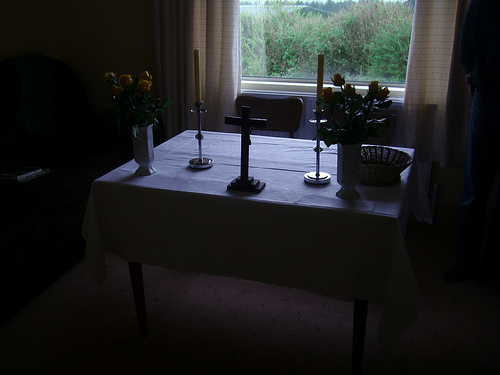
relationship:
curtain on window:
[160, 0, 243, 135] [241, 5, 410, 90]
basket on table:
[357, 146, 411, 189] [87, 128, 416, 361]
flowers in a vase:
[97, 70, 164, 128] [131, 126, 166, 179]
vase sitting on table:
[131, 126, 166, 179] [87, 128, 416, 361]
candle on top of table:
[191, 47, 204, 101] [87, 128, 416, 361]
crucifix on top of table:
[219, 103, 270, 197] [87, 128, 416, 361]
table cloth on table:
[78, 125, 427, 337] [87, 128, 416, 361]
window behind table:
[241, 5, 410, 90] [87, 128, 416, 361]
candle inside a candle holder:
[191, 47, 204, 101] [190, 102, 214, 170]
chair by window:
[232, 91, 301, 139] [241, 5, 410, 90]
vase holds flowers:
[131, 126, 166, 179] [97, 70, 164, 128]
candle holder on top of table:
[190, 102, 214, 170] [87, 128, 416, 361]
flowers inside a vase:
[97, 70, 164, 128] [131, 126, 166, 179]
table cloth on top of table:
[78, 125, 427, 337] [87, 128, 416, 361]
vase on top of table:
[131, 126, 166, 179] [87, 128, 416, 361]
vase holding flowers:
[131, 126, 166, 179] [97, 70, 164, 128]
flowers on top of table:
[97, 70, 164, 128] [87, 128, 416, 361]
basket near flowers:
[357, 146, 411, 189] [307, 71, 399, 149]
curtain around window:
[160, 0, 243, 135] [241, 5, 410, 90]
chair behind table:
[232, 91, 301, 139] [87, 128, 416, 361]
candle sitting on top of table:
[191, 47, 204, 101] [87, 128, 416, 361]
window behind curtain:
[241, 5, 410, 90] [160, 0, 243, 135]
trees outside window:
[296, 21, 397, 70] [241, 5, 410, 90]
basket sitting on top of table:
[357, 146, 411, 189] [87, 128, 416, 361]